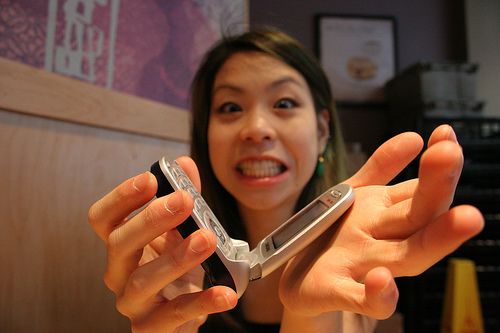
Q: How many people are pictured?
A: One.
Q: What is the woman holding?
A: A cell phone.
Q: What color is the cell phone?
A: SIlver and black.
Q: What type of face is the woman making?
A: A silly face.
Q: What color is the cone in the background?
A: Yellow.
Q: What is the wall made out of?
A: Wood.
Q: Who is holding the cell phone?
A: The woman.